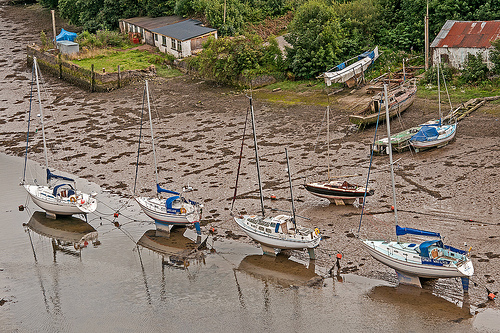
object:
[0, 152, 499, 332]
water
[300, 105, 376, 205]
boat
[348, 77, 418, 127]
boat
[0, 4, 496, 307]
sand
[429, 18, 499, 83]
house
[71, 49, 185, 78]
grass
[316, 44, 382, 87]
boat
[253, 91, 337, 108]
grass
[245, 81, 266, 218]
mast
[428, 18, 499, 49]
roof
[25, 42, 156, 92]
fence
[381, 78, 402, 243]
mast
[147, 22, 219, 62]
shed